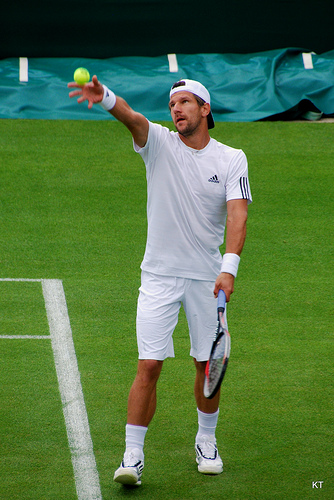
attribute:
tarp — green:
[3, 46, 323, 125]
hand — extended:
[62, 73, 109, 106]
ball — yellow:
[71, 61, 94, 93]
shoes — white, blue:
[111, 440, 229, 491]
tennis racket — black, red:
[194, 289, 246, 402]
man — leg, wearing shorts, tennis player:
[61, 53, 257, 498]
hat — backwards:
[166, 77, 214, 103]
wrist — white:
[218, 247, 248, 281]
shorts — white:
[130, 271, 237, 366]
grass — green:
[5, 110, 330, 490]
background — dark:
[2, 6, 333, 79]